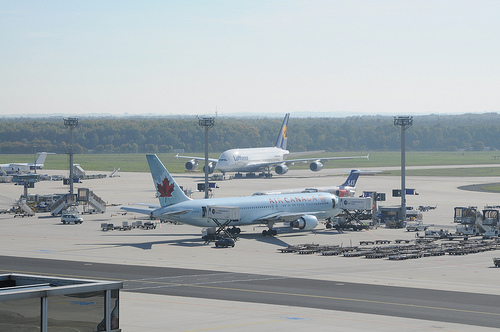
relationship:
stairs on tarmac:
[77, 187, 106, 212] [3, 171, 498, 324]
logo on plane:
[268, 194, 327, 204] [119, 153, 340, 238]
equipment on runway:
[277, 234, 499, 260] [3, 165, 498, 314]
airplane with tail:
[120, 154, 344, 237] [130, 154, 197, 225]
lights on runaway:
[389, 112, 416, 238] [126, 242, 404, 317]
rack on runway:
[339, 248, 371, 260] [1, 249, 498, 324]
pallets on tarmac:
[278, 237, 498, 264] [0, 181, 498, 331]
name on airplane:
[269, 195, 328, 205] [120, 154, 344, 237]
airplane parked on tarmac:
[120, 154, 344, 237] [2, 246, 483, 328]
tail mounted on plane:
[146, 154, 191, 207] [87, 140, 417, 256]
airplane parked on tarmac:
[120, 154, 344, 237] [3, 230, 490, 329]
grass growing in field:
[414, 167, 497, 176] [76, 153, 146, 170]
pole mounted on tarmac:
[393, 113, 413, 226] [124, 252, 471, 329]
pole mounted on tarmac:
[194, 114, 215, 197] [124, 252, 471, 329]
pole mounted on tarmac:
[65, 118, 75, 195] [124, 252, 471, 329]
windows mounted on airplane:
[239, 204, 293, 209] [176, 166, 340, 237]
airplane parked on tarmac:
[173, 113, 370, 176] [124, 252, 471, 329]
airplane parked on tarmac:
[120, 154, 344, 237] [122, 155, 344, 240]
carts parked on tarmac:
[101, 215, 159, 234] [124, 252, 471, 329]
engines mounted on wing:
[274, 159, 325, 172] [248, 150, 371, 166]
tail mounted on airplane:
[147, 152, 190, 206] [119, 151, 343, 234]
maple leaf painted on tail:
[154, 173, 176, 198] [147, 152, 190, 206]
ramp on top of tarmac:
[213, 214, 227, 230] [125, 258, 482, 330]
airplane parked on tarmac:
[120, 154, 344, 237] [124, 252, 471, 329]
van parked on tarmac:
[62, 209, 84, 224] [0, 254, 500, 331]